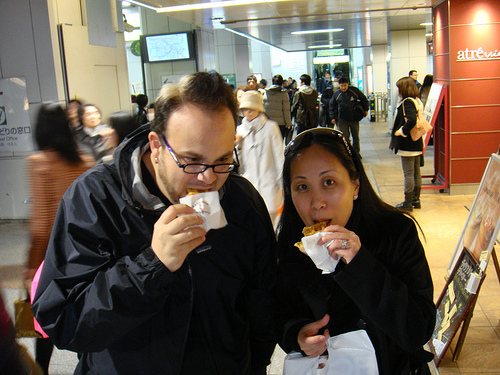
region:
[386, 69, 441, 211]
A woman with a tan purse waiting.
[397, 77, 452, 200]
A red sign in front of a business.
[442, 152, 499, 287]
A sign with frozen drinks on it.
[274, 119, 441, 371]
A woman eating food.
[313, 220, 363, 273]
A silver ring on the woman.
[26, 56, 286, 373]
A man eating food.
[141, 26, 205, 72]
A television with a map on it.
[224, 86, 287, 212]
A woman in a white coat and white hat.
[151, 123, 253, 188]
A pair of eyeglasses on the man.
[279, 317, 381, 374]
A white plastic sack.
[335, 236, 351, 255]
ring on a persons finger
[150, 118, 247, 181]
glasses on a persons face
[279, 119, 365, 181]
glasses on a persons head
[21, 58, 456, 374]
two people eating food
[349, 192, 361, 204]
earring in a persons ear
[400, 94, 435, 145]
purse on a persons shoulder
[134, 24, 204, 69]
television on a wall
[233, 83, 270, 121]
hat on a persons head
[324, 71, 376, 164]
person with a coat walking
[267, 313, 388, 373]
white bag in a persons hand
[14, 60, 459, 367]
a man and a woman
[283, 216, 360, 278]
woman has food in her hand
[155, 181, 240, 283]
man has food in his hand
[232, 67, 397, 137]
a group of people standing around in the background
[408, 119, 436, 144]
a woman's purse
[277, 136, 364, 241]
a woman's purse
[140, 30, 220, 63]
a monitor mounted on a wall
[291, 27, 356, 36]
lights in the ceiling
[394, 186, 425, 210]
black leather boots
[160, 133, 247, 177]
man has a pair of eyeglasses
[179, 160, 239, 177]
Black eye glasses worn by the man eating.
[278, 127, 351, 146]
Sunglasses on the woman's head eating.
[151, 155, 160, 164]
Earring in the man's ear that is eating.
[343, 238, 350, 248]
Silver ring on the woman's finger that is eating.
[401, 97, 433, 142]
Beige purse of girl standing near the red wall.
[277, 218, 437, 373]
Black jacket the woman that is eating is wearing.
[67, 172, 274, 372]
Black jacket of the man that is eating.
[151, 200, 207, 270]
The hand of the man that is eating.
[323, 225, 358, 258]
The hand holding the food of the woman that is eating.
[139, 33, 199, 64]
Flat screen monitor/tv on the wall on the left.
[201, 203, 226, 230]
part of a white tissue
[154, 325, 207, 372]
part of a black jacket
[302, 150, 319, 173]
head of a woman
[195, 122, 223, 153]
head of a man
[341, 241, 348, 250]
part of a ring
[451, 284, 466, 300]
part of a portrait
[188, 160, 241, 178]
spectacle of the man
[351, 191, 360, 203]
part of an earring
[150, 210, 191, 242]
right hand of the man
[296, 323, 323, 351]
right hand of the woman